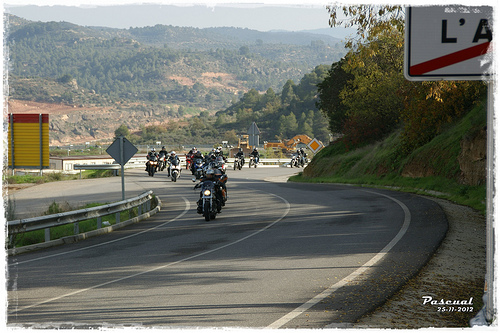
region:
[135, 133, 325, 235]
riding on two wheels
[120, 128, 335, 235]
leading the pack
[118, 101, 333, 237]
biker crew riding the valley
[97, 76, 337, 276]
riding in a pack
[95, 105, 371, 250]
A great day to ride bikes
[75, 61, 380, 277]
racing to the finish line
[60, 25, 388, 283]
riding through the valley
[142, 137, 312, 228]
a group of motorcyclists riding up a hill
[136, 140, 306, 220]
motorcyclists heading towards the camera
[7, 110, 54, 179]
a large red and yellow road sign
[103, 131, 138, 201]
back of a diamond shaped road sign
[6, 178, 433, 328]
white lines marking lanes on a road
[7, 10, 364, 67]
rolling hills in the background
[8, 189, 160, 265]
crash barrier in the center of a road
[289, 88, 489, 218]
grassy bank next to a road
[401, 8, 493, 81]
corner of a road sign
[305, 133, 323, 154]
a yellow and white diamond shape street sign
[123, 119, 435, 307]
the cyclists are riding down the highway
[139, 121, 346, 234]
this is a group of motorcycle riders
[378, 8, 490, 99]
a bottom part of traffic sign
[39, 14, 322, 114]
the mountain side behind the riders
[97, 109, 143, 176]
the back of a sign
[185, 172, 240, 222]
the light is on this motorcycle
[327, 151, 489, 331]
the side of the road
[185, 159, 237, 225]
this is a motorbike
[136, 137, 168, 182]
this is a motorbike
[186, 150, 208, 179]
this is a motorbike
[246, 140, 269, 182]
this is a motorbike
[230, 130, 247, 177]
this is a motorbike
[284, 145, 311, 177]
this is a motorbike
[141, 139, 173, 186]
this is a motorbike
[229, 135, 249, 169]
a man on a bike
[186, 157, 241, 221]
a man on a bike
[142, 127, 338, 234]
they are all riding motorcycles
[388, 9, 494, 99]
a white street sign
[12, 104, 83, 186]
a yellow and red sign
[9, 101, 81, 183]
the back of the sign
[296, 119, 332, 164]
a white and orange sign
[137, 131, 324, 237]
there are many motorcycles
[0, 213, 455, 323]
shadows on the ground from trees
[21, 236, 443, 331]
the road is paved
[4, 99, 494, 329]
motorcycles on a winding road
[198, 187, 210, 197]
headlight on motorcycle is on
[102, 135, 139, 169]
sign on poleis diamond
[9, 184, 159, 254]
small rail by grass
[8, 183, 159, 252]
rail by grass is small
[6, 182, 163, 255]
rail by grass is metal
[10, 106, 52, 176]
large sign above road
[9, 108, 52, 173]
sign above road is red and yellow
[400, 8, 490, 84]
white sign on pole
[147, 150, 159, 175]
motorcycle travels down road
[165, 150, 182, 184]
motorcycle travels down road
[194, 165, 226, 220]
motorcycle travels down road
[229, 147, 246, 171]
motorcycle travels down road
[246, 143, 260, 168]
motorcycle travels down road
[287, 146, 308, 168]
motorcycle travels down road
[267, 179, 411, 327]
stripe is white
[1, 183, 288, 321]
stripe is white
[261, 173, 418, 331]
stripe is white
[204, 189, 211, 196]
headlight belongs to motorcycle